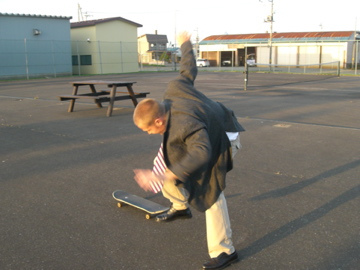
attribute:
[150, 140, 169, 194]
tie — red, white, striped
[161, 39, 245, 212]
suit coat — gray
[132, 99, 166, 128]
hair — brush cut, short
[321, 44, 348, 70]
garage door — white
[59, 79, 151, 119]
table — wooden, vacant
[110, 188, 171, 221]
skateboard — black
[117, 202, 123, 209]
wheel — yellow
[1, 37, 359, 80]
fence — chain link, tall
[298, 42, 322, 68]
garage door — white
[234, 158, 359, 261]
shadow — man's legs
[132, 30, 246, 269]
young boy — stomping ground, falling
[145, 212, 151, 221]
wheel — yellow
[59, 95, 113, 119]
picnic bench — empty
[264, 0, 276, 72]
utility pole — tall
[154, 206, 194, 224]
shoe — black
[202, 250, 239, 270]
shoe — black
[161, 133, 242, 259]
pants — khaki, tan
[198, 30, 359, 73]
building — white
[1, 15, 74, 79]
building — blue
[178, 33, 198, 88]
arm — extended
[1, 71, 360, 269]
ground — paved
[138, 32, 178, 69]
building — white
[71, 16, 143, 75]
building — pale yellow